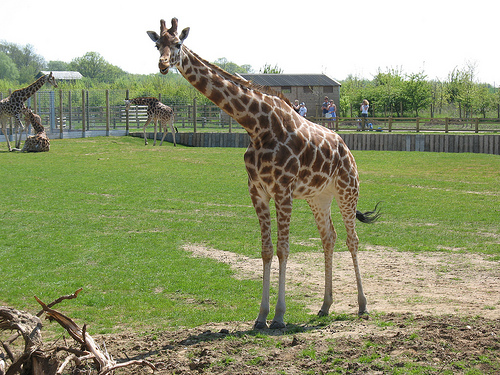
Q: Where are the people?
A: Behind the fence.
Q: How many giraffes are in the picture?
A: Four.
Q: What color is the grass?
A: Green.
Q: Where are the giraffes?
A: In a pen.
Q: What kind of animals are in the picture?
A: Giraffes.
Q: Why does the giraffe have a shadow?
A: The sun is shining.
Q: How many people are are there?
A: Five.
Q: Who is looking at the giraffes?
A: People.